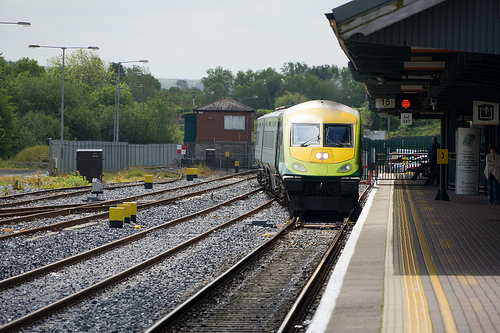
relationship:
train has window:
[251, 98, 361, 216] [322, 120, 356, 150]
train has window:
[251, 98, 361, 216] [288, 120, 320, 150]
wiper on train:
[299, 133, 319, 149] [239, 93, 367, 207]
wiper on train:
[334, 128, 350, 144] [239, 93, 367, 207]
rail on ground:
[0, 167, 367, 331] [2, 165, 370, 330]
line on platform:
[399, 170, 462, 331] [306, 165, 498, 330]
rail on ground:
[0, 194, 271, 331] [2, 165, 370, 330]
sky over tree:
[0, 1, 355, 78] [132, 96, 188, 146]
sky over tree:
[0, 1, 355, 78] [199, 63, 236, 106]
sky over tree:
[0, 1, 355, 78] [230, 65, 283, 110]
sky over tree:
[0, 1, 355, 78] [122, 64, 162, 105]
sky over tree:
[0, 1, 355, 78] [44, 43, 111, 100]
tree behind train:
[132, 96, 188, 146] [251, 98, 361, 216]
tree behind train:
[199, 63, 236, 106] [251, 98, 361, 216]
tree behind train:
[230, 65, 283, 110] [251, 98, 361, 216]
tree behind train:
[122, 64, 162, 105] [251, 98, 361, 216]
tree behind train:
[44, 43, 111, 100] [251, 98, 361, 216]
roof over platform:
[319, 7, 404, 69] [306, 165, 498, 330]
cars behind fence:
[383, 137, 457, 188] [362, 140, 444, 180]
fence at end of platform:
[362, 140, 444, 180] [306, 165, 498, 330]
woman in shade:
[478, 140, 483, 193] [375, 42, 484, 319]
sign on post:
[433, 147, 448, 166] [433, 143, 449, 201]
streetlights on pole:
[26, 38, 106, 53] [58, 43, 69, 136]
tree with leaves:
[7, 76, 52, 141] [99, 67, 109, 85]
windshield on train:
[292, 121, 347, 152] [251, 98, 361, 216]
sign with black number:
[374, 96, 397, 108] [381, 97, 391, 106]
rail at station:
[0, 167, 367, 331] [325, 1, 499, 192]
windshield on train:
[291, 124, 352, 148] [242, 97, 365, 202]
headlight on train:
[332, 162, 354, 177] [239, 98, 362, 220]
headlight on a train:
[292, 162, 305, 174] [255, 95, 365, 220]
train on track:
[251, 98, 361, 216] [0, 165, 169, 208]